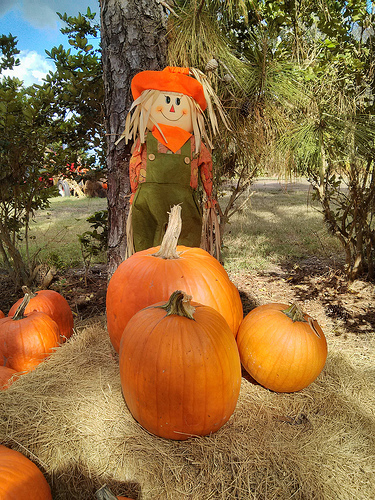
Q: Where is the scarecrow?
A: Leaning against tree.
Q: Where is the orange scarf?
A: Around scarecrow's neck.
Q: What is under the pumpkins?
A: Brown hay.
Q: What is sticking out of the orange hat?
A: Straw-colored hair.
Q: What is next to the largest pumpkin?
A: Small pumpkin.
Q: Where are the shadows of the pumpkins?
A: On the hay.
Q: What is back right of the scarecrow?
A: Green and yellow straw.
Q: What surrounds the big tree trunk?
A: Straw and darker brown dirt.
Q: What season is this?
A: Autumn.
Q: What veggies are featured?
A: Pumpkins.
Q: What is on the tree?
A: Scarecrow.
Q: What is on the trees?
A: Pine needles.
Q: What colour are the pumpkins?
A: Orange.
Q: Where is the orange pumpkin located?
A: A patch.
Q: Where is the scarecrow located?
A: Pumpkin patch.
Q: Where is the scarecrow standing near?
A: A tree.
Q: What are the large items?
A: Pumpkins.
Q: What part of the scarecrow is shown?
A: Face.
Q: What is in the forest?
A: House.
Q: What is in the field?
A: Dry grass.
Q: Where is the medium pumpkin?
A: On hay.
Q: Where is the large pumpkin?
A: On hay.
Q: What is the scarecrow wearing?
A: Orange hat.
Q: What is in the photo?
A: Pumpkins.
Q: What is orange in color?
A: The pumpkins.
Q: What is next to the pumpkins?
A: Leaves.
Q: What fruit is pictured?
A: Pumpkin.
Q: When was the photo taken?
A: Daytime.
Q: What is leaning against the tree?
A: Scarecrow.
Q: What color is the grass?
A: Green.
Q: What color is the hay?
A: Beige.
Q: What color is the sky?
A: Blue.